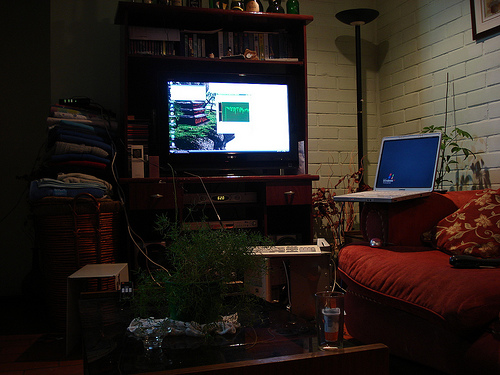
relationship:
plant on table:
[127, 204, 274, 318] [79, 285, 390, 374]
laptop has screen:
[331, 133, 443, 203] [375, 136, 442, 187]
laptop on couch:
[331, 133, 443, 203] [339, 191, 499, 374]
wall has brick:
[307, 2, 498, 232] [261, 1, 499, 231]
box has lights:
[56, 98, 91, 108] [63, 98, 77, 105]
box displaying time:
[185, 194, 259, 204] [215, 196, 226, 202]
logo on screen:
[382, 172, 396, 183] [375, 136, 442, 187]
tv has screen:
[162, 75, 298, 168] [169, 83, 290, 154]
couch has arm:
[339, 191, 499, 374] [360, 189, 495, 244]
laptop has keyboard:
[331, 133, 443, 203] [336, 187, 429, 198]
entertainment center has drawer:
[113, 5, 314, 242] [264, 182, 313, 205]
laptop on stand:
[331, 133, 443, 203] [360, 189, 495, 244]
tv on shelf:
[162, 75, 298, 168] [121, 176, 320, 181]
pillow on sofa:
[418, 190, 498, 258] [337, 189, 499, 374]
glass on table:
[313, 292, 344, 350] [79, 285, 390, 374]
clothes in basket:
[30, 104, 117, 197] [42, 193, 116, 275]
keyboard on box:
[245, 244, 326, 256] [245, 258, 330, 315]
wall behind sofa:
[307, 2, 498, 232] [337, 189, 499, 374]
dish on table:
[271, 319, 307, 336] [79, 285, 390, 374]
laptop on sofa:
[331, 133, 443, 203] [337, 189, 499, 374]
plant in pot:
[127, 204, 274, 318] [166, 282, 221, 323]